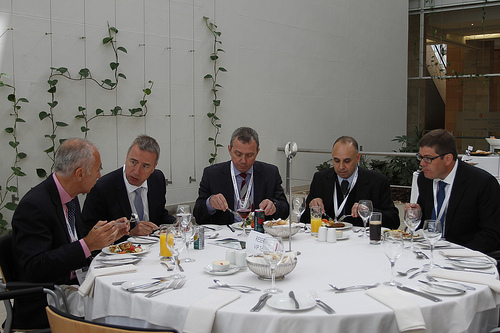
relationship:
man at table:
[12, 133, 133, 332] [76, 216, 500, 332]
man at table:
[79, 133, 181, 250] [76, 216, 500, 332]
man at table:
[194, 123, 293, 226] [76, 216, 500, 332]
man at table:
[301, 135, 402, 231] [76, 216, 500, 332]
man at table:
[404, 127, 499, 258] [76, 216, 500, 332]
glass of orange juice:
[309, 204, 324, 238] [308, 216, 322, 233]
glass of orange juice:
[157, 226, 176, 258] [159, 232, 174, 257]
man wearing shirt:
[12, 133, 133, 332] [50, 172, 94, 280]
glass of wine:
[237, 196, 255, 228] [234, 207, 252, 219]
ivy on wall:
[0, 15, 226, 242] [3, 1, 405, 243]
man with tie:
[194, 123, 293, 226] [238, 171, 250, 207]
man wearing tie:
[404, 127, 499, 258] [433, 180, 447, 230]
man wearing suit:
[12, 133, 133, 332] [11, 171, 97, 332]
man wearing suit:
[79, 133, 181, 250] [78, 159, 181, 255]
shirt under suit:
[50, 172, 94, 280] [11, 171, 97, 332]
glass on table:
[157, 226, 176, 258] [76, 216, 500, 332]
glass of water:
[175, 202, 193, 230] [176, 212, 193, 228]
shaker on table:
[316, 224, 328, 244] [76, 216, 500, 332]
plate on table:
[270, 287, 319, 314] [76, 216, 500, 332]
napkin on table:
[362, 283, 428, 332] [76, 216, 500, 332]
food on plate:
[109, 243, 143, 255] [102, 242, 153, 258]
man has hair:
[404, 127, 499, 258] [415, 126, 458, 160]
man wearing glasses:
[404, 127, 499, 258] [411, 147, 446, 163]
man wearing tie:
[194, 123, 293, 226] [238, 171, 250, 207]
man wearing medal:
[301, 135, 402, 231] [328, 158, 362, 221]